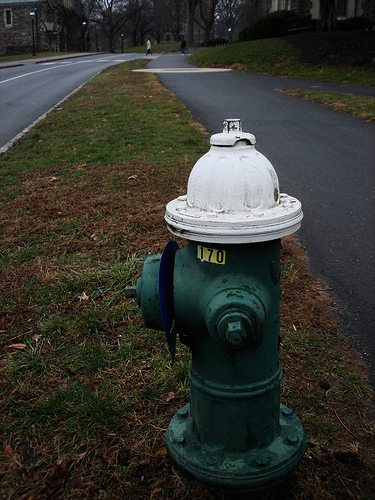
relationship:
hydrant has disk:
[121, 114, 307, 493] [156, 239, 181, 362]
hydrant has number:
[121, 114, 307, 493] [194, 242, 227, 269]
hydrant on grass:
[121, 114, 307, 493] [2, 57, 373, 492]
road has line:
[2, 49, 153, 156] [0, 50, 132, 85]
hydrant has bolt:
[121, 114, 307, 493] [223, 319, 250, 348]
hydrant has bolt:
[121, 114, 307, 493] [220, 114, 243, 137]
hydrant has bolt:
[121, 114, 307, 493] [121, 280, 140, 303]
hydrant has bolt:
[121, 114, 307, 493] [280, 401, 297, 420]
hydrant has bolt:
[121, 114, 307, 493] [282, 430, 301, 446]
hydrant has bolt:
[121, 114, 307, 493] [176, 405, 190, 419]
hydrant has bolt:
[121, 114, 307, 493] [169, 431, 187, 445]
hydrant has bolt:
[121, 114, 307, 493] [202, 454, 223, 469]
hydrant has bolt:
[121, 114, 307, 493] [252, 451, 271, 470]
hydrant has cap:
[121, 114, 307, 493] [161, 112, 307, 248]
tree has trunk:
[186, 1, 221, 48] [200, 28, 213, 53]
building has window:
[2, 1, 74, 59] [4, 8, 16, 29]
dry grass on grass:
[6, 167, 342, 341] [2, 57, 373, 492]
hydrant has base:
[121, 114, 307, 493] [121, 239, 309, 490]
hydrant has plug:
[121, 114, 307, 493] [200, 288, 270, 351]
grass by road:
[2, 57, 373, 492] [2, 49, 153, 156]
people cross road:
[142, 34, 189, 58] [2, 49, 153, 156]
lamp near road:
[27, 8, 39, 59] [2, 49, 153, 156]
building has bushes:
[2, 1, 74, 59] [4, 42, 42, 61]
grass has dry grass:
[2, 57, 373, 492] [6, 167, 342, 341]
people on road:
[142, 34, 189, 58] [2, 49, 153, 156]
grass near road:
[2, 57, 373, 492] [2, 49, 153, 156]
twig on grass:
[331, 403, 364, 444] [2, 57, 373, 492]